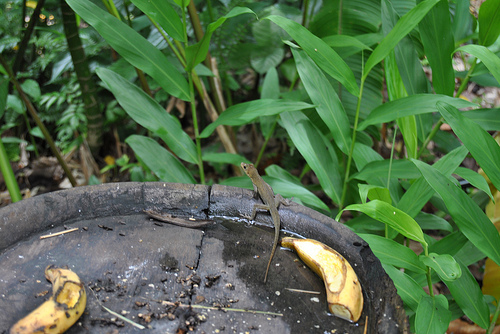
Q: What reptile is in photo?
A: Lizard.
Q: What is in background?
A: Greenery.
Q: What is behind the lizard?
A: Banana.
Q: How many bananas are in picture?
A: 2.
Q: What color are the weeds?
A: Green.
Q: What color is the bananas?
A: Yellow.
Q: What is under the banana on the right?
A: Water.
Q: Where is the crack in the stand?
A: Middle.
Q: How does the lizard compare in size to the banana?
A: Same.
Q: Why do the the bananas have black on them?
A: Rotten.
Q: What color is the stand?
A: Black.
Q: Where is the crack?
A: On the stand.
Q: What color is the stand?
A: Black.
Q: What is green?
A: Leaves.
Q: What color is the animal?
A: Brown.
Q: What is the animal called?
A: Lizard.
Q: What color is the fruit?
A: Yellow.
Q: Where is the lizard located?
A: On the barrel.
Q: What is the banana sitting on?
A: A barrel.